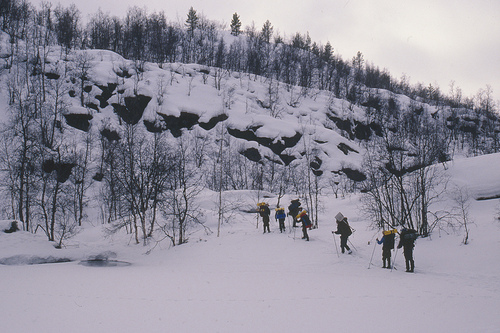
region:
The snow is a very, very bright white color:
[271, 281, 291, 313]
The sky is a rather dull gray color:
[426, 23, 456, 40]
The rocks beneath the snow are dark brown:
[259, 87, 281, 124]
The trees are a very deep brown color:
[131, 139, 166, 199]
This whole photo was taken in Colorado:
[65, 30, 415, 281]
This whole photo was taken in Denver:
[60, 13, 418, 324]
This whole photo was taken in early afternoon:
[93, 11, 412, 299]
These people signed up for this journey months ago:
[98, 14, 332, 299]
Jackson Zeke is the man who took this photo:
[113, 17, 408, 324]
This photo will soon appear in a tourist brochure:
[98, 25, 393, 307]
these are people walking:
[273, 205, 423, 274]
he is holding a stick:
[365, 242, 382, 263]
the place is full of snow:
[169, 258, 326, 330]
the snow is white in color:
[232, 266, 308, 331]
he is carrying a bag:
[383, 227, 395, 247]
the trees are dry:
[41, 152, 182, 231]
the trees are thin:
[125, 154, 192, 234]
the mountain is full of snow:
[155, 67, 253, 132]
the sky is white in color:
[409, 7, 454, 52]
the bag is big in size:
[397, 227, 420, 240]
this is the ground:
[103, 267, 320, 326]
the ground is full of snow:
[161, 268, 321, 319]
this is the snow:
[143, 268, 315, 330]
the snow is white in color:
[146, 270, 298, 332]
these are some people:
[253, 197, 422, 272]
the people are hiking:
[256, 195, 436, 267]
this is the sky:
[334, 7, 498, 43]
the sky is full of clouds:
[344, 6, 482, 61]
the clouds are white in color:
[353, 11, 437, 49]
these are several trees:
[118, 20, 225, 54]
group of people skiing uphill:
[251, 194, 421, 280]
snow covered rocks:
[48, 49, 424, 183]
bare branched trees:
[0, 131, 236, 251]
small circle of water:
[77, 244, 134, 274]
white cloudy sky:
[33, 0, 498, 115]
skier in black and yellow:
[376, 225, 398, 270]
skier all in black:
[394, 224, 419, 272]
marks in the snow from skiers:
[416, 269, 497, 297]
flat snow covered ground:
[0, 276, 422, 331]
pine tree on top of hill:
[227, 11, 244, 36]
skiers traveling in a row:
[233, 168, 433, 278]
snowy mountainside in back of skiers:
[20, 25, 492, 236]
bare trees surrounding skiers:
[17, 41, 447, 281]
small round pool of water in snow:
[60, 247, 136, 272]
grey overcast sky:
[320, 10, 490, 75]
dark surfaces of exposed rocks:
[55, 60, 290, 180]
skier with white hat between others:
[303, 192, 390, 259]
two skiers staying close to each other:
[360, 205, 440, 277]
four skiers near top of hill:
[251, 180, 316, 245]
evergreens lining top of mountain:
[176, 7, 373, 84]